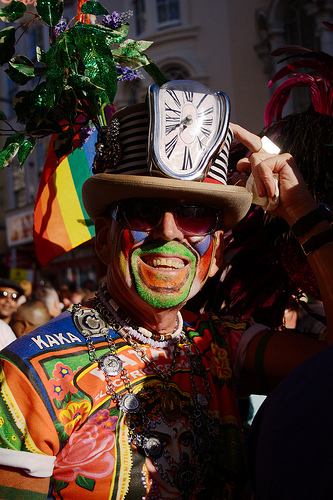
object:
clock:
[147, 77, 230, 183]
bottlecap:
[73, 308, 109, 339]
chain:
[102, 366, 133, 403]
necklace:
[89, 280, 184, 350]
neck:
[103, 264, 185, 336]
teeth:
[145, 258, 186, 270]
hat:
[81, 80, 252, 232]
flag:
[33, 98, 116, 268]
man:
[0, 78, 333, 499]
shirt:
[0, 277, 270, 499]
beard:
[153, 297, 169, 309]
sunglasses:
[120, 199, 219, 237]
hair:
[103, 203, 120, 223]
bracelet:
[290, 203, 333, 256]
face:
[111, 198, 214, 311]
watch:
[286, 204, 333, 260]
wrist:
[280, 190, 320, 241]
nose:
[151, 203, 185, 245]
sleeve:
[210, 311, 270, 396]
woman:
[125, 382, 210, 499]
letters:
[30, 330, 82, 352]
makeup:
[112, 231, 216, 311]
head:
[94, 201, 226, 321]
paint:
[173, 249, 185, 257]